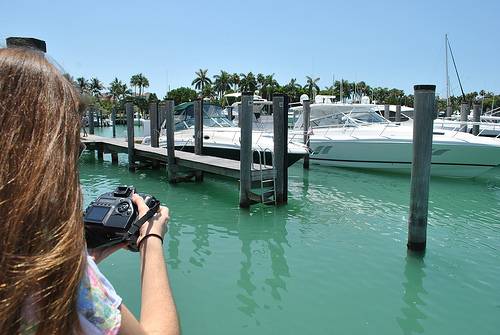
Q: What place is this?
A: It is a harbor.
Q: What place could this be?
A: It is a harbor.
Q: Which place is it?
A: It is a harbor.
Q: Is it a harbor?
A: Yes, it is a harbor.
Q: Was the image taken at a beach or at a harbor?
A: It was taken at a harbor.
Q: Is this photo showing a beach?
A: No, the picture is showing a harbor.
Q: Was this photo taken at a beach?
A: No, the picture was taken in a harbor.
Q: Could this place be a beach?
A: No, it is a harbor.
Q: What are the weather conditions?
A: It is clear.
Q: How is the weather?
A: It is clear.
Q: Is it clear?
A: Yes, it is clear.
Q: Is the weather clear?
A: Yes, it is clear.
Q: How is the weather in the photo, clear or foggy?
A: It is clear.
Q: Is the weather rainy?
A: No, it is clear.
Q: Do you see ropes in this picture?
A: No, there are no ropes.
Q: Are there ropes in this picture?
A: No, there are no ropes.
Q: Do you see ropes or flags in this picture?
A: No, there are no ropes or flags.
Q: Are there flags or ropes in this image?
A: No, there are no ropes or flags.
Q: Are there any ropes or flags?
A: No, there are no ropes or flags.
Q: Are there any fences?
A: No, there are no fences.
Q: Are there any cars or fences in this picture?
A: No, there are no fences or cars.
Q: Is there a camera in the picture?
A: Yes, there is a camera.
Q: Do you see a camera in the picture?
A: Yes, there is a camera.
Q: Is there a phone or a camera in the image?
A: Yes, there is a camera.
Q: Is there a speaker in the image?
A: No, there are no speakers.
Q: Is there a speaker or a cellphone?
A: No, there are no speakers or cell phones.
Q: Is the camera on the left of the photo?
A: Yes, the camera is on the left of the image.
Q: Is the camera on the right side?
A: No, the camera is on the left of the image.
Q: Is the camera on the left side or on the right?
A: The camera is on the left of the image.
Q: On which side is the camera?
A: The camera is on the left of the image.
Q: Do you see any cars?
A: No, there are no cars.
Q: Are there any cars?
A: No, there are no cars.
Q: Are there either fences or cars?
A: No, there are no cars or fences.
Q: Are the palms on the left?
A: Yes, the palms are on the left of the image.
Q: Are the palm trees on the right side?
A: No, the palm trees are on the left of the image.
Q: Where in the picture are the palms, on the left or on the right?
A: The palms are on the left of the image.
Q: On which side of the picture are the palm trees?
A: The palm trees are on the left of the image.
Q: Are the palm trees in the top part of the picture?
A: Yes, the palm trees are in the top of the image.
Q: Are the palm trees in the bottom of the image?
A: No, the palm trees are in the top of the image.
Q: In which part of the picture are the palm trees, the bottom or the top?
A: The palm trees are in the top of the image.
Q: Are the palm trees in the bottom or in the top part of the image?
A: The palm trees are in the top of the image.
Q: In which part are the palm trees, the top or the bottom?
A: The palm trees are in the top of the image.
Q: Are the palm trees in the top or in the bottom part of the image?
A: The palm trees are in the top of the image.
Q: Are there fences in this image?
A: No, there are no fences.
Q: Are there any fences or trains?
A: No, there are no fences or trains.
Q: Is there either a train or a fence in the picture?
A: No, there are no fences or trains.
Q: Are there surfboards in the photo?
A: No, there are no surfboards.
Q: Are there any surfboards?
A: No, there are no surfboards.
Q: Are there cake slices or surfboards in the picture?
A: No, there are no surfboards or cake slices.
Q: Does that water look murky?
A: Yes, the water is murky.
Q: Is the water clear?
A: No, the water is murky.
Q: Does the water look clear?
A: No, the water is murky.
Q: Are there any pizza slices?
A: No, there are no pizza slices.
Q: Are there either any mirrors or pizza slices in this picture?
A: No, there are no pizza slices or mirrors.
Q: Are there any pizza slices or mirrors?
A: No, there are no pizza slices or mirrors.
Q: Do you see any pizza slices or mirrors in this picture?
A: No, there are no pizza slices or mirrors.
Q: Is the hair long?
A: Yes, the hair is long.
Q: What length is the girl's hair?
A: The hair is long.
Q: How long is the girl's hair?
A: The hair is long.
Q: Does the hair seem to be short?
A: No, the hair is long.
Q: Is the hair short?
A: No, the hair is long.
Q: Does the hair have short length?
A: No, the hair is long.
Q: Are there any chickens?
A: No, there are no chickens.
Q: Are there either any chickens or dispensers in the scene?
A: No, there are no chickens or dispensers.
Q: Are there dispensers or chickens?
A: No, there are no chickens or dispensers.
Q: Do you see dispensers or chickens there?
A: No, there are no chickens or dispensers.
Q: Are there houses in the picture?
A: No, there are no houses.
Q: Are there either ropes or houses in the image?
A: No, there are no houses or ropes.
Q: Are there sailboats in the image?
A: Yes, there is a sailboat.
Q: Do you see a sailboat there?
A: Yes, there is a sailboat.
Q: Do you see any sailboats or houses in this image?
A: Yes, there is a sailboat.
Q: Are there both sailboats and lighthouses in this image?
A: No, there is a sailboat but no lighthouses.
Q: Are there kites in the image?
A: No, there are no kites.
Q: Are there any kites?
A: No, there are no kites.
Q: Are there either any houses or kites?
A: No, there are no kites or houses.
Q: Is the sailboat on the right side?
A: Yes, the sailboat is on the right of the image.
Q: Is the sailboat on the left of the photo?
A: No, the sailboat is on the right of the image.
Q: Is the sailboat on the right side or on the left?
A: The sailboat is on the right of the image.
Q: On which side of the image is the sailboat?
A: The sailboat is on the right of the image.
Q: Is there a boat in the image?
A: Yes, there is a boat.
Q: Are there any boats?
A: Yes, there is a boat.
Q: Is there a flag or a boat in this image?
A: Yes, there is a boat.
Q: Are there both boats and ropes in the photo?
A: No, there is a boat but no ropes.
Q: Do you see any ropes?
A: No, there are no ropes.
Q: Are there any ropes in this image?
A: No, there are no ropes.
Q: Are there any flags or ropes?
A: No, there are no ropes or flags.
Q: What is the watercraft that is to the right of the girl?
A: The watercraft is a boat.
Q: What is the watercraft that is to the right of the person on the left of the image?
A: The watercraft is a boat.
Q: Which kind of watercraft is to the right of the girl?
A: The watercraft is a boat.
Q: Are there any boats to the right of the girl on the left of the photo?
A: Yes, there is a boat to the right of the girl.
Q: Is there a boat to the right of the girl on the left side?
A: Yes, there is a boat to the right of the girl.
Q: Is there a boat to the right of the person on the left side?
A: Yes, there is a boat to the right of the girl.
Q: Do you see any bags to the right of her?
A: No, there is a boat to the right of the girl.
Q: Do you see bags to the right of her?
A: No, there is a boat to the right of the girl.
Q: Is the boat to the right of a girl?
A: Yes, the boat is to the right of a girl.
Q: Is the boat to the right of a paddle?
A: No, the boat is to the right of a girl.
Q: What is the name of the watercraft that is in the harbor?
A: The watercraft is a boat.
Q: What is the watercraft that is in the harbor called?
A: The watercraft is a boat.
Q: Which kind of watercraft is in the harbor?
A: The watercraft is a boat.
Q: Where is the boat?
A: The boat is in the harbor.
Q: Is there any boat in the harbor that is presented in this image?
A: Yes, there is a boat in the harbor.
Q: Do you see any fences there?
A: No, there are no fences.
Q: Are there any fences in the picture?
A: No, there are no fences.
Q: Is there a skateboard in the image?
A: No, there are no skateboards.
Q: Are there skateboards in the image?
A: No, there are no skateboards.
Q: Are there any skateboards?
A: No, there are no skateboards.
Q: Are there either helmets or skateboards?
A: No, there are no skateboards or helmets.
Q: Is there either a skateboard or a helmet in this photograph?
A: No, there are no skateboards or helmets.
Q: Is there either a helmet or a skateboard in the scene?
A: No, there are no skateboards or helmets.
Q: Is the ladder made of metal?
A: Yes, the ladder is made of metal.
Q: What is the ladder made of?
A: The ladder is made of metal.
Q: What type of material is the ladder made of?
A: The ladder is made of metal.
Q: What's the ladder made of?
A: The ladder is made of metal.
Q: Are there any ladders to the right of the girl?
A: Yes, there is a ladder to the right of the girl.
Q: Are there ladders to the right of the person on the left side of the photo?
A: Yes, there is a ladder to the right of the girl.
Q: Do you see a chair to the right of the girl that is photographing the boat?
A: No, there is a ladder to the right of the girl.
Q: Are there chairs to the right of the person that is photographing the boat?
A: No, there is a ladder to the right of the girl.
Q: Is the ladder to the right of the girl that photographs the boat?
A: Yes, the ladder is to the right of the girl.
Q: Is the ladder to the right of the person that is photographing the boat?
A: Yes, the ladder is to the right of the girl.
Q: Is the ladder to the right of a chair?
A: No, the ladder is to the right of the girl.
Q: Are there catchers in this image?
A: No, there are no catchers.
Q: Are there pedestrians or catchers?
A: No, there are no catchers or pedestrians.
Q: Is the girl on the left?
A: Yes, the girl is on the left of the image.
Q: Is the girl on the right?
A: No, the girl is on the left of the image.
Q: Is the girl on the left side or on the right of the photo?
A: The girl is on the left of the image.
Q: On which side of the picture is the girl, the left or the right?
A: The girl is on the left of the image.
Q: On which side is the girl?
A: The girl is on the left of the image.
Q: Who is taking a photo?
A: The girl is taking a photo.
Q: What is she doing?
A: The girl is taking a photo.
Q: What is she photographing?
A: The girl is photographing the boat.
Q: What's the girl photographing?
A: The girl is photographing the boat.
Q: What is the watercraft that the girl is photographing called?
A: The watercraft is a boat.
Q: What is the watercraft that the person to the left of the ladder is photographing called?
A: The watercraft is a boat.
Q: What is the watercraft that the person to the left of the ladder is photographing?
A: The watercraft is a boat.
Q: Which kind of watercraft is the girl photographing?
A: The girl is photographing the boat.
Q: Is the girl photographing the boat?
A: Yes, the girl is photographing the boat.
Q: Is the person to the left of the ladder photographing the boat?
A: Yes, the girl is photographing the boat.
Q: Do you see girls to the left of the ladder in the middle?
A: Yes, there is a girl to the left of the ladder.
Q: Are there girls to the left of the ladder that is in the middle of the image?
A: Yes, there is a girl to the left of the ladder.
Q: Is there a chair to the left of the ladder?
A: No, there is a girl to the left of the ladder.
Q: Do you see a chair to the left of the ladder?
A: No, there is a girl to the left of the ladder.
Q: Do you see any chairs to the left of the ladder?
A: No, there is a girl to the left of the ladder.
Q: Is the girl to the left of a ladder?
A: Yes, the girl is to the left of a ladder.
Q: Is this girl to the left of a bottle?
A: No, the girl is to the left of a ladder.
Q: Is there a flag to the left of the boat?
A: No, there is a girl to the left of the boat.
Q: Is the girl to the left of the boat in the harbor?
A: Yes, the girl is to the left of the boat.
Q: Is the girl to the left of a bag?
A: No, the girl is to the left of the boat.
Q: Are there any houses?
A: No, there are no houses.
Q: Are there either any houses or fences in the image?
A: No, there are no houses or fences.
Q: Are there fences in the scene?
A: No, there are no fences.